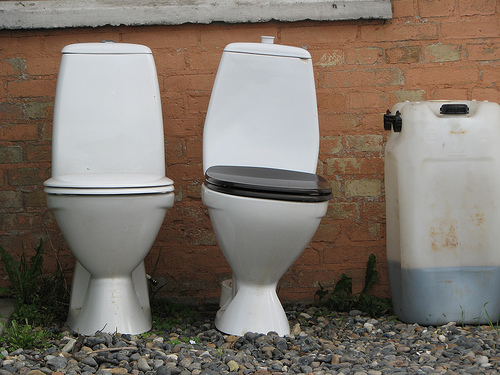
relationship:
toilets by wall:
[44, 38, 379, 323] [319, 38, 454, 158]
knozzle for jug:
[351, 96, 422, 192] [384, 210, 476, 314]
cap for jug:
[425, 96, 473, 114] [384, 210, 476, 314]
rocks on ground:
[326, 310, 396, 365] [244, 280, 476, 369]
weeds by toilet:
[16, 229, 75, 315] [190, 28, 317, 214]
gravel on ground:
[167, 331, 229, 371] [244, 280, 476, 369]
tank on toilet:
[45, 40, 181, 136] [190, 28, 317, 214]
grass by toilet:
[171, 295, 231, 321] [190, 28, 317, 214]